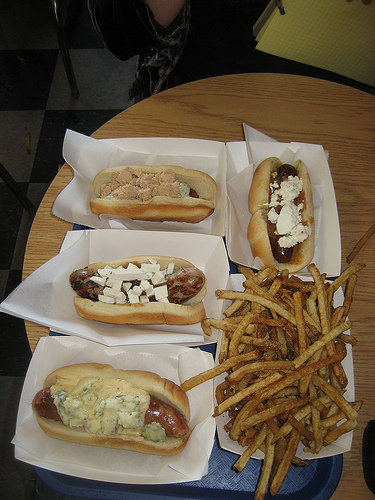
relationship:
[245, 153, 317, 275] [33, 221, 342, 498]
hotdog on tray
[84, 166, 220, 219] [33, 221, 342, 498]
hotdog on tray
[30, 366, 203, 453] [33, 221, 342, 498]
hotdog on tray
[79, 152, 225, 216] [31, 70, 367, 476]
food on table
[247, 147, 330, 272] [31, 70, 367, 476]
food on table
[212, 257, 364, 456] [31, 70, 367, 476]
food on table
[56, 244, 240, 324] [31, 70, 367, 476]
food on table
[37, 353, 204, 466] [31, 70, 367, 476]
food on table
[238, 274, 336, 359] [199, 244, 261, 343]
french fries in container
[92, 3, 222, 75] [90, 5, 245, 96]
black shirt on person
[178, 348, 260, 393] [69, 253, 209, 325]
french fry touching hot dog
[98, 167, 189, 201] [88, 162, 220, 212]
topping served on brat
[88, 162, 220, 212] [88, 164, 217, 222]
brat served on bun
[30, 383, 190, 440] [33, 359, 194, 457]
brat/toppings/bun served on bun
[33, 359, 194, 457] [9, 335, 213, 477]
bun served on paper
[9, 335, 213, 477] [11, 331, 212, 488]
paper inside container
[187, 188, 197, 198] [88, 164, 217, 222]
brat served on bun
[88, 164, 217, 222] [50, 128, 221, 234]
bun served on paper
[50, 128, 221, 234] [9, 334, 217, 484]
paper inside paper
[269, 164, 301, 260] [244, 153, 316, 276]
brat and bun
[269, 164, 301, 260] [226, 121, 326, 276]
brat on paper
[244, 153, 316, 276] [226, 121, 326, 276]
bun on paper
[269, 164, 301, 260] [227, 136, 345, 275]
brat in container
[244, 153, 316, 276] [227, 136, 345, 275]
bun in container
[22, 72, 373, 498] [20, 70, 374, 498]
wood grain of a table top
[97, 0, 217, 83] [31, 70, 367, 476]
person sitting at table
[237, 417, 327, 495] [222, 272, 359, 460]
fries hanging container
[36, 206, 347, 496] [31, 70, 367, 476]
blue tray hanging over table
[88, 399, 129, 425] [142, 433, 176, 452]
toppings on bun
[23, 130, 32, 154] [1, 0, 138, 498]
garbage on ground